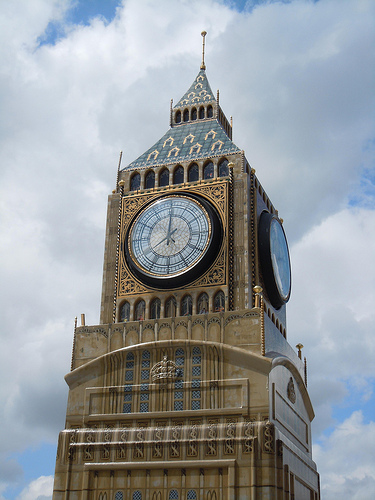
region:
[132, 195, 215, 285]
the tower has a clock on the side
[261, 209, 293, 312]
the tower has a clock on the side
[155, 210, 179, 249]
the dials are black in color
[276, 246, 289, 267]
the dials are black in color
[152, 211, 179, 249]
the dials are made of metal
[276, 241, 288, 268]
the dials are made of metal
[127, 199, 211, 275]
the clock has lines for numerals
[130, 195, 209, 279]
the clock face is white in color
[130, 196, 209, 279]
the clock has a glass cover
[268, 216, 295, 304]
the clock has a glass cover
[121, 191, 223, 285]
the clock is on the tower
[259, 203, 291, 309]
the clock is on the tower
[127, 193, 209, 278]
the clock has a gold rim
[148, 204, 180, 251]
the clock has black dials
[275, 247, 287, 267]
the clock has black dials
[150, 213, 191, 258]
the clock has an inner circle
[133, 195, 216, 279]
the clock has a white clockface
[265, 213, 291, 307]
the clock has a white clockfac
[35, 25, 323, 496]
this is a tall building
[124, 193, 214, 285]
this is a clock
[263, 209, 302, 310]
this is a clock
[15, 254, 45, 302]
this is a cloud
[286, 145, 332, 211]
this is a cloud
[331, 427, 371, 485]
this is a cloud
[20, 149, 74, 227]
this is a cloud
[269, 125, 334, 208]
this is a cloud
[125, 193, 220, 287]
clock on the side of the tower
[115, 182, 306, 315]
two clocks on either side of the tower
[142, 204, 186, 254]
two black clock hands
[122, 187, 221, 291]
black and blue clock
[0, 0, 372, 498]
white clouds in the sky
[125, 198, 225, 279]
black marks around the circumference of the clock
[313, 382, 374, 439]
bright blue sky poking through the clouds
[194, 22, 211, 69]
steeple on the top of the tower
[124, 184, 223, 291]
clock indicating it's about 8 o'clock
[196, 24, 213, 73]
top of the clock tower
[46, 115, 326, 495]
a bronze clock tower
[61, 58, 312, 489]
a bronze clock tower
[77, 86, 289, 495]
a bronze clock tower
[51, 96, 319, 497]
a bronze clock tower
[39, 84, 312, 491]
a bronze clock tower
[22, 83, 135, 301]
the sky is cloudy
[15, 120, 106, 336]
the sky is cloudy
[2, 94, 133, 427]
the sky is cloudy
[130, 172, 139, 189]
glass window in the building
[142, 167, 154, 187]
glass window in the building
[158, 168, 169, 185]
glass window in the building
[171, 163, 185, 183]
glass window in the building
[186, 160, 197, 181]
glass window in the building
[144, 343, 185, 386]
crown fixture in building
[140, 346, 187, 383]
crown fixture in building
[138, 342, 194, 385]
crown fixture in building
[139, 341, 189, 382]
crown fixture in building